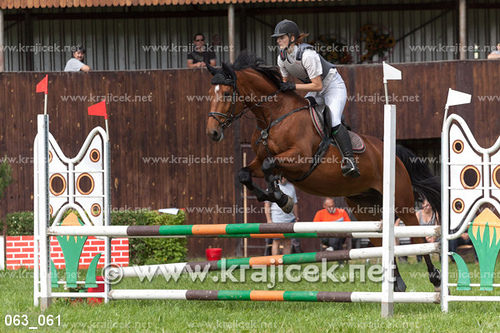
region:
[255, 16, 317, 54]
woman's helmet is black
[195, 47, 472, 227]
the horse is brown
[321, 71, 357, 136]
woman's pants are white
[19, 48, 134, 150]
the flags are red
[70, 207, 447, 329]
the sticks are brown green orange and white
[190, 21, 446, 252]
the horse is jumping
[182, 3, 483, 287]
the woman is riding horse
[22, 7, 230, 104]
people are watching woman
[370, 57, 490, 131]
the flags are white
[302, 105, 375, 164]
the saddle is brown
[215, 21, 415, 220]
woman riding a jumping horse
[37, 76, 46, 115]
small red flag on pole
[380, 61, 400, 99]
small white flag on pole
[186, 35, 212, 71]
man in black shirt watching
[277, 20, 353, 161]
woman wearing black riding helmet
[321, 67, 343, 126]
white pants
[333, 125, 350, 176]
black leather riding boot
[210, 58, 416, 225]
brown horse jumping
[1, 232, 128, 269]
small red brick wall behind obstacle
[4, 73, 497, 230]
dark brown wooden wall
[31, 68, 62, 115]
red flag on fence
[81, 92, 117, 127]
red flag on fence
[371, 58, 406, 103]
white flag on fence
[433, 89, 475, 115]
white flag on fence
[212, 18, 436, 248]
horse and rider jumping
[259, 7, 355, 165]
rider on brown horse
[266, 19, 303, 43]
black riding helmet on person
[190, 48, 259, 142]
head of brown horse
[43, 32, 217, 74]
spectators watching horse jump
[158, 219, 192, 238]
green section of fence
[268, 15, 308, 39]
a black helmet on a woman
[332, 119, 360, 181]
black boots on a woman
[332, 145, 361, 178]
a stirrup supporting a woman's foot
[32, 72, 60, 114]
a red flag on top of a pole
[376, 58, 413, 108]
a white flag on top of a pole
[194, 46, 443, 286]
a brown and black horse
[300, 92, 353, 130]
a saddle on a horse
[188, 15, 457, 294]
a woman riding a horse over a jump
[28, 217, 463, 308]
poles on a horse jump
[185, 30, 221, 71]
a spectator in a black shirt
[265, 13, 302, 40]
Woman wears black hat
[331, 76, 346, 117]
Woman wears white pants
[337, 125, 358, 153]
Woman wears black boots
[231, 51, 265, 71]
Horse has brown mane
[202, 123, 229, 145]
Horse's nose is brown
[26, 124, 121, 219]
White gate in grass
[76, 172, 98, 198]
yellow circle in gate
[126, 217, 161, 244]
Purple color on pole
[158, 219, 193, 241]
Green color on pole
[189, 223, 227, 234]
Orange color on pole